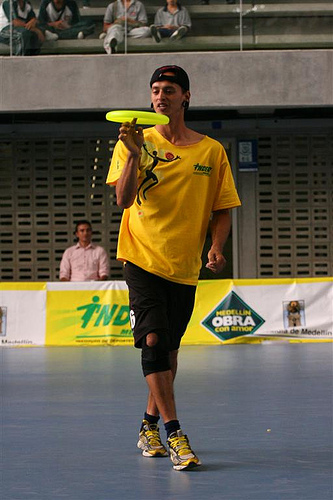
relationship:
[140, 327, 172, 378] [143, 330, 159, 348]
brace around knee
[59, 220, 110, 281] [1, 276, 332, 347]
man sitting behind banner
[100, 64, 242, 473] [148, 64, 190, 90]
man wearing hat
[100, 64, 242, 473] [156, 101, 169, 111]
man has mouth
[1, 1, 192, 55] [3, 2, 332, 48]
people sitting on bleachers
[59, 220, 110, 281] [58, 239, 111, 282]
man wearing shirt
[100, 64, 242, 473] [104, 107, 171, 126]
man holding frisbee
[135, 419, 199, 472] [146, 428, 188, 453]
sneakers with laces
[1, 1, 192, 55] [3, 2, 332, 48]
people sitting in bleachers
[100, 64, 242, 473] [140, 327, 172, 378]
man wearing brace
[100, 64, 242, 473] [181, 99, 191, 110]
man wearing earring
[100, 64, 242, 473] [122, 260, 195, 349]
man wearing shorts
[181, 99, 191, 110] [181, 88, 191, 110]
earring inside of ear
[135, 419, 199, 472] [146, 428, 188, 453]
sneakers have laces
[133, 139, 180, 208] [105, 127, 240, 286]
design on shirt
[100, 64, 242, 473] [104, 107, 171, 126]
man balancing frisbee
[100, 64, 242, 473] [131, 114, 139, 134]
man has finger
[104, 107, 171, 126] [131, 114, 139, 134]
frisbee balancing on finger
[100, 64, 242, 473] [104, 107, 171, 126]
man spinning frisbee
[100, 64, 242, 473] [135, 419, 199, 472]
man wearing sneakers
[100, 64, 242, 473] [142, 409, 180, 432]
man wearing socks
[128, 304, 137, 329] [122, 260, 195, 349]
number on side of shorts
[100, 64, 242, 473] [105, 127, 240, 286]
man wearing shirt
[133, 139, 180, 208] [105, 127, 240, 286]
design printed on shirt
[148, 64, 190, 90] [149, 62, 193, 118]
hat on top of head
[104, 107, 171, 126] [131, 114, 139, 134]
frisbee spinning on finger